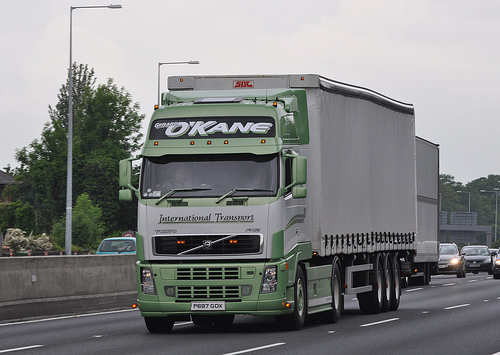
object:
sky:
[0, 0, 500, 184]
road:
[0, 269, 499, 354]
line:
[358, 316, 400, 329]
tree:
[0, 62, 145, 236]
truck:
[116, 73, 421, 335]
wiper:
[213, 186, 275, 204]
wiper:
[153, 185, 211, 207]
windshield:
[138, 151, 284, 202]